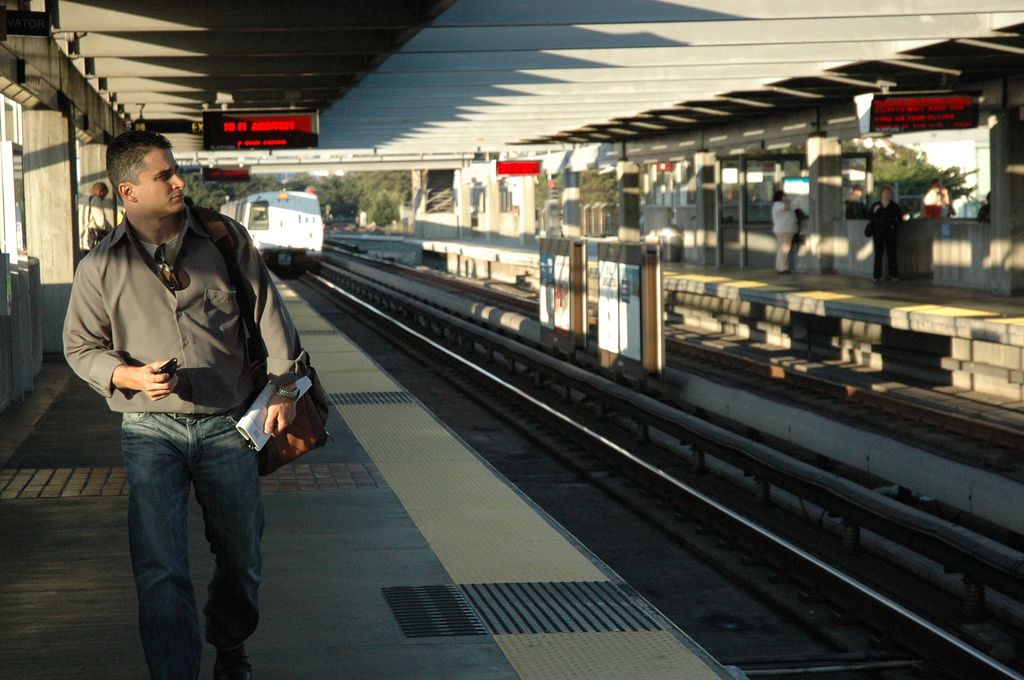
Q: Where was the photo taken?
A: At a train stop.